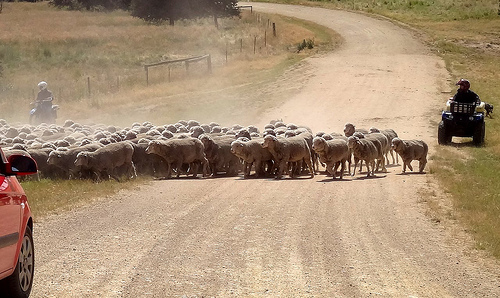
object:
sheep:
[310, 136, 352, 180]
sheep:
[73, 142, 135, 183]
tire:
[17, 231, 39, 297]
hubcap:
[16, 234, 33, 298]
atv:
[21, 94, 61, 125]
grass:
[429, 143, 500, 256]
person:
[453, 79, 480, 103]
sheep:
[347, 136, 380, 176]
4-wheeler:
[437, 102, 492, 145]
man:
[451, 78, 480, 110]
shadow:
[395, 171, 425, 175]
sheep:
[391, 137, 431, 174]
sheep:
[229, 131, 259, 169]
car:
[1, 139, 36, 297]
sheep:
[47, 142, 99, 180]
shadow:
[246, 170, 273, 178]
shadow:
[284, 170, 314, 180]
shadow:
[316, 178, 353, 183]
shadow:
[354, 170, 384, 180]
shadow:
[359, 169, 387, 174]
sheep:
[262, 133, 315, 179]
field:
[0, 0, 500, 297]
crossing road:
[23, 0, 500, 298]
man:
[32, 80, 51, 120]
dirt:
[33, 3, 491, 297]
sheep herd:
[0, 118, 428, 182]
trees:
[0, 0, 240, 27]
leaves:
[54, 0, 247, 26]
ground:
[0, 0, 499, 298]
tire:
[437, 118, 458, 144]